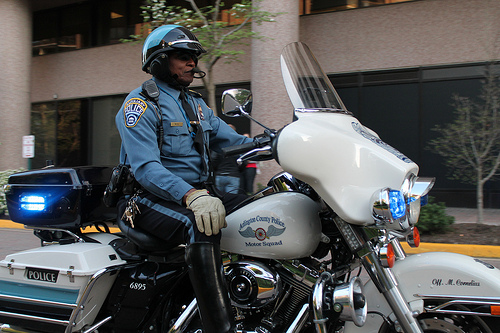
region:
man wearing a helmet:
[125, 9, 208, 89]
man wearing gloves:
[161, 168, 230, 236]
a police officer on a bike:
[2, 10, 484, 312]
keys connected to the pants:
[110, 183, 155, 235]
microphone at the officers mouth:
[167, 60, 209, 89]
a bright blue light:
[6, 182, 73, 224]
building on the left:
[10, 12, 465, 224]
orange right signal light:
[364, 240, 401, 272]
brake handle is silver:
[233, 144, 275, 169]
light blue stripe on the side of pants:
[125, 191, 202, 243]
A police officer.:
[99, 21, 241, 326]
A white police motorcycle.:
[9, 93, 490, 331]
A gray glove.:
[171, 181, 232, 241]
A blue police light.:
[15, 185, 62, 227]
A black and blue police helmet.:
[134, 16, 200, 81]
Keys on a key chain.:
[118, 195, 140, 225]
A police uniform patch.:
[120, 95, 148, 128]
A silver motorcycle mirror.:
[218, 85, 255, 120]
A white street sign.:
[17, 130, 48, 165]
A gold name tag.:
[167, 117, 186, 127]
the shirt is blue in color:
[117, 68, 259, 208]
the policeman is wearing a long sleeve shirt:
[115, 79, 257, 224]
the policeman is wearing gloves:
[183, 183, 232, 238]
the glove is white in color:
[187, 188, 229, 238]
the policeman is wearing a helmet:
[138, 21, 204, 83]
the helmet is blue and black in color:
[140, 25, 205, 74]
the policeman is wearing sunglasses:
[164, 48, 201, 63]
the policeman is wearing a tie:
[174, 90, 215, 169]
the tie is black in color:
[175, 92, 210, 154]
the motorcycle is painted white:
[3, 40, 499, 325]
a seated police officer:
[102, 24, 269, 331]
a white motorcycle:
[11, 39, 490, 324]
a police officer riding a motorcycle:
[6, 23, 496, 328]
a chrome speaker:
[309, 269, 369, 326]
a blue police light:
[374, 184, 410, 226]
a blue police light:
[14, 189, 51, 223]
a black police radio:
[137, 74, 170, 151]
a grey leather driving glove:
[179, 189, 229, 241]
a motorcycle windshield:
[271, 35, 352, 119]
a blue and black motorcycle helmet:
[132, 17, 207, 74]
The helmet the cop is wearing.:
[142, 23, 204, 59]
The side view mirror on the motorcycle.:
[217, 81, 282, 143]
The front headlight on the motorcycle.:
[400, 174, 432, 222]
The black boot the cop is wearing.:
[190, 231, 239, 323]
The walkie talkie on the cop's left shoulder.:
[143, 79, 160, 106]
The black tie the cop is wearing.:
[182, 90, 215, 160]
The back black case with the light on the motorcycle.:
[1, 166, 115, 232]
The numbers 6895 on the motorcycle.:
[128, 274, 151, 289]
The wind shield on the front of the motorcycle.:
[269, 37, 352, 109]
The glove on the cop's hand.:
[180, 183, 233, 233]